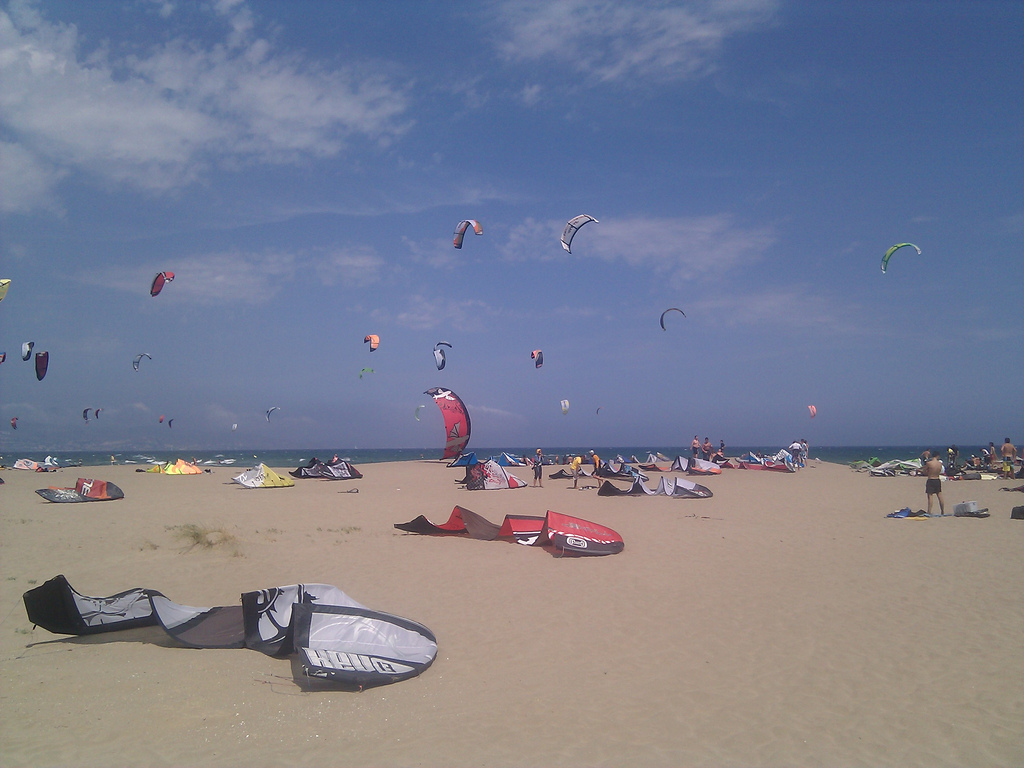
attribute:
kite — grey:
[22, 575, 447, 731]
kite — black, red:
[400, 493, 626, 569]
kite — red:
[420, 371, 477, 471]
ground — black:
[3, 474, 999, 762]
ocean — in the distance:
[5, 440, 1009, 464]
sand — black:
[6, 477, 1009, 765]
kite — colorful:
[31, 352, 51, 382]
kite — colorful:
[146, 270, 178, 297]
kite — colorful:
[447, 216, 486, 252]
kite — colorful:
[554, 209, 599, 260]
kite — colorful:
[876, 233, 928, 282]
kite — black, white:
[23, 574, 436, 689]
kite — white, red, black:
[390, 503, 625, 560]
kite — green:
[878, 233, 924, 273]